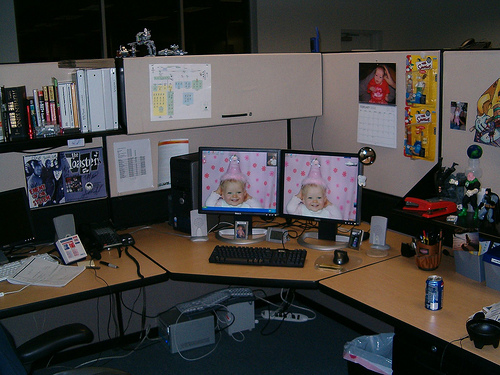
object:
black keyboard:
[203, 237, 310, 277]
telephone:
[73, 219, 123, 261]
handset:
[77, 222, 98, 254]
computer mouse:
[323, 240, 363, 274]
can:
[424, 273, 443, 311]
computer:
[197, 145, 364, 267]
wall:
[254, 4, 497, 107]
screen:
[196, 139, 279, 225]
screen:
[280, 148, 360, 222]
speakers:
[187, 210, 387, 249]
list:
[112, 136, 154, 193]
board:
[103, 119, 288, 198]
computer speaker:
[364, 202, 401, 266]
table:
[2, 197, 499, 368]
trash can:
[303, 313, 386, 373]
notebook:
[6, 251, 86, 286]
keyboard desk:
[202, 233, 323, 286]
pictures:
[202, 151, 352, 218]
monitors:
[198, 145, 366, 227]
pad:
[315, 250, 364, 273]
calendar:
[356, 60, 401, 150]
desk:
[15, 211, 485, 357]